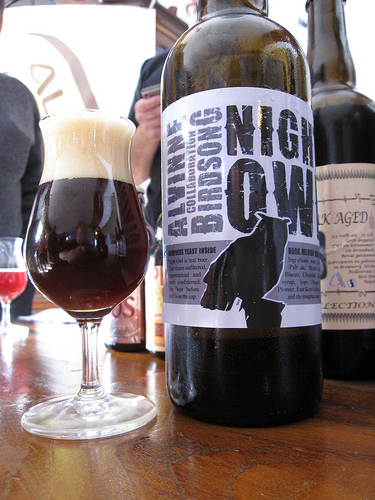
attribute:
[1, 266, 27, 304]
liquid — red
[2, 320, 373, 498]
wooden table — tan and brown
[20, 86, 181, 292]
drink — brown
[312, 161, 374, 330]
label — tan 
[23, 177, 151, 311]
beer — brown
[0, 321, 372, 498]
table — tan, brown, wooden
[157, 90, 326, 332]
label — white, grey and white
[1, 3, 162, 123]
banner — white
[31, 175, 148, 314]
beer — brown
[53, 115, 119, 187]
head — white